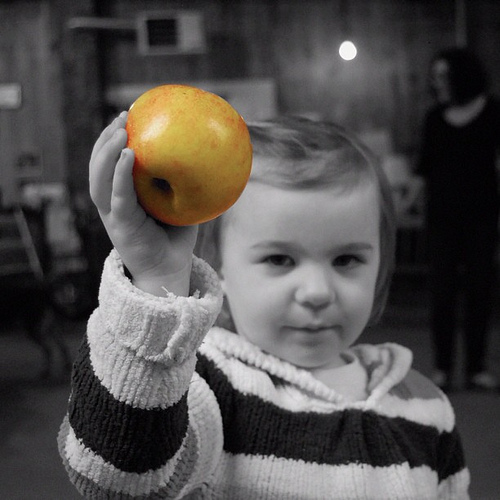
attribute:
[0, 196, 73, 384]
chair — large, wooden, curved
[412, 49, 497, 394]
woman — standing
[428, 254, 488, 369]
pants — black  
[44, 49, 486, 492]
child — young  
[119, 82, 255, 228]
apple — delicious , red 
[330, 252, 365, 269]
eye — the left eye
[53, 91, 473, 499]
little girl — little 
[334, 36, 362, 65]
light — shining 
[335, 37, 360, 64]
light bulb — shining  , bright  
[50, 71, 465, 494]
child — young  , posing  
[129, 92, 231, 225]
apple — fresh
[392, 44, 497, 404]
woman — standing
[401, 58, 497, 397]
woman — an adult  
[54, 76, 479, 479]
sweater child — young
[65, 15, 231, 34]
wooden shelf — long , high , wooden 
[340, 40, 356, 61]
light bulb — on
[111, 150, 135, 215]
finger — pinky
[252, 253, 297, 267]
eye — right eye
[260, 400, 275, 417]
knitting — small  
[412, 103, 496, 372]
clothes — dark 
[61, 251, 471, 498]
sweater — soft  , stripped  , with stripes 